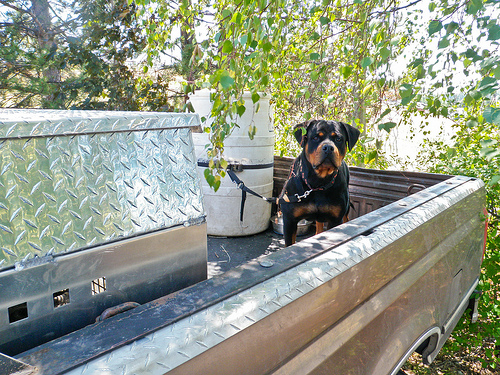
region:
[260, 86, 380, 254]
this is a dog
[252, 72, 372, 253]
the dog is a rott weiler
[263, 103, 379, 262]
the dog is black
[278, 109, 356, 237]
brown spots on the dog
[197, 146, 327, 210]
leash attached to dog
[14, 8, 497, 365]
dog on a truck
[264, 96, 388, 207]
black and brown dog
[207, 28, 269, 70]
green and yellow leaves in trees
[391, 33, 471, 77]
green and yellow leaves in trees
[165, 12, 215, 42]
green and yellow leaves in trees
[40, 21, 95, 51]
green and yellow leaves in trees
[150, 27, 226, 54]
green and yellow leaves in trees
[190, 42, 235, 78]
green and yellow leaves in trees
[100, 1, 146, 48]
green and yellow leaves in trees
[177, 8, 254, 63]
green and yellow leaves in trees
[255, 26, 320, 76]
green and yellow leaves in trees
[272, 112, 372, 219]
An imposing looking dog colored black and brown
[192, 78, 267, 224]
A large white plastic barrel with a leash tied around it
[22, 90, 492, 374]
The bed of a light brown pickup truck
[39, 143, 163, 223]
A silver surface with a crosshatch pattern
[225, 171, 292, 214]
A sretched black dog leash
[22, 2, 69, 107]
A tree trunk with surrounding branches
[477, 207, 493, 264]
A rear taillight seen from the side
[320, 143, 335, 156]
A small black dog nose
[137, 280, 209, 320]
A black metal strip with orange rusted spots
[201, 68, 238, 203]
A hanging leaf-colored branch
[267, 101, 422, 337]
a dog in a truck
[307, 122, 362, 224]
a large dog in a truck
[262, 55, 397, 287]
a large brown and black dog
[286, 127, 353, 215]
brown and black dog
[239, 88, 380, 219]
a dog on a leash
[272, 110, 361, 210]
a dog wearing a collar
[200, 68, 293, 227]
a barrel in a truck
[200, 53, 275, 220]
a white barrel in truck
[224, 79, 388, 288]
a dog tied to a barrell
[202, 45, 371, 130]
leaves on a tree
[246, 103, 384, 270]
This is a dog